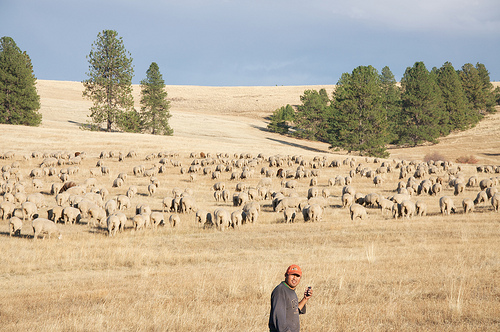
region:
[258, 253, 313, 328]
Man holding a phone.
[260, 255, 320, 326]
Man wearing orange hat.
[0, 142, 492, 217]
Sheep in a field.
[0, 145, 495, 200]
Grazing sheep in a field.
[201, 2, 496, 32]
Clear blue sky.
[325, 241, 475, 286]
Brown grass in a field.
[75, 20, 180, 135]
Two trees in a group by themselves.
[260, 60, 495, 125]
A Group of trees.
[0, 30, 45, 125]
One lone evergreen tree.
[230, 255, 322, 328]
Man in a field.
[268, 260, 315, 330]
this is a man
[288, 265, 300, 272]
this is a cap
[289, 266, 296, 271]
the cap is red in color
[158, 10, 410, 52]
this is the sky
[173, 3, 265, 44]
the sky is blue in color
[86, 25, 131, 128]
this is a tree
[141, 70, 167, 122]
the tree has green leaves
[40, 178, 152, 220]
these are sheep feeding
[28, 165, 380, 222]
the sheep are many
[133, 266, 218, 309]
this is a vegetation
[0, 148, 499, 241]
a heard of sheep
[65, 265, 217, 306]
yellow grass in field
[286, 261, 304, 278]
orange cap on mans head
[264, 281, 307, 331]
a blue sweat shirt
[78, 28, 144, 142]
tall green tree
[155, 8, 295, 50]
a blue sky above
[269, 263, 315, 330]
a man standing in field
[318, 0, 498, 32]
a wispy white cloud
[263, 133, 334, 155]
shadow of tree on the ground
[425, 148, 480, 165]
small shrubs in background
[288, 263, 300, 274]
the man is wearing a cap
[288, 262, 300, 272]
the cap is orange in color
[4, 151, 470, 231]
these are flock on the field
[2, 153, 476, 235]
the flock is brown in color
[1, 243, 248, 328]
the grass is brown in color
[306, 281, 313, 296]
the man is holding a cell phone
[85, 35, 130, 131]
this tree is tall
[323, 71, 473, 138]
the trees are green in color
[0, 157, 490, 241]
the flock are feeding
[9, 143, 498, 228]
a herd of sheep eating the grass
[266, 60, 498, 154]
a group of trees standing together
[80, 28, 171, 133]
two more trees standing together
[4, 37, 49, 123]
another tree on the side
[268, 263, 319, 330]
a man standing around and watching the sheep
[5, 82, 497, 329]
a big field with dry grass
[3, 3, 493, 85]
the blue sky above everything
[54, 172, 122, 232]
a cluster of hungry sheep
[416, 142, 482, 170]
two little bushes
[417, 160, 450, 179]
another cluster of sheep